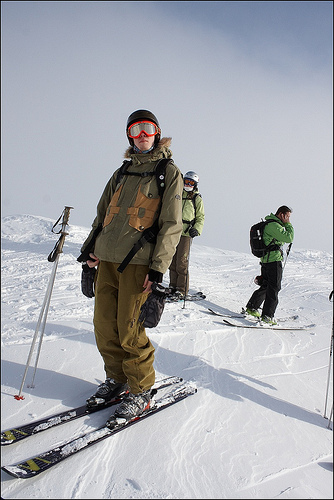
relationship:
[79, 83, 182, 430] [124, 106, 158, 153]
man wearing helmet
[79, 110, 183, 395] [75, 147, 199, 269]
man wearing jacket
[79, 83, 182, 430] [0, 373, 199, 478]
man wearing skis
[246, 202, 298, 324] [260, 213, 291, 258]
man wearing jacket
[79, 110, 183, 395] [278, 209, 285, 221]
man talking on cellphone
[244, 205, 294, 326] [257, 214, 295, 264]
man wearing coat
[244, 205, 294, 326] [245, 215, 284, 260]
man wearing backpack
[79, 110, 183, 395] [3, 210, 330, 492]
man on mountain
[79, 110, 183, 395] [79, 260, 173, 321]
man has gloves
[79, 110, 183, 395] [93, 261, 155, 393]
man has jeans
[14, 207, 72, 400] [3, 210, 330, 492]
skier's poles in mountain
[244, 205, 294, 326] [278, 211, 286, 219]
man in cell phone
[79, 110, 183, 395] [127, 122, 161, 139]
man wearing eyewear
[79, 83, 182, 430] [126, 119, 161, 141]
man wearing goggles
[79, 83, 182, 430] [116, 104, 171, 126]
man wearing helmet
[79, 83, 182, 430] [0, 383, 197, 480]
man wearing skis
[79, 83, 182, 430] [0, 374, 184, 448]
man wearing skis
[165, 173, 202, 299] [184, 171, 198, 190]
man wearing helmet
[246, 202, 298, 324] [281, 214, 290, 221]
man has hand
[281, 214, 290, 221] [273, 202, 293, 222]
hand on head